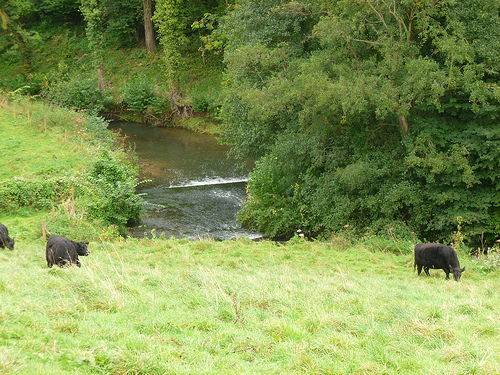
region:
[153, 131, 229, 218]
this is a water body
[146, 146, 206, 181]
the water is calm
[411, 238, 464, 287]
this is a cow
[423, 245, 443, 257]
the cow is black in color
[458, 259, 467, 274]
this is the horn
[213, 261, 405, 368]
this is a grass area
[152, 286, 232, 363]
the grass is green in color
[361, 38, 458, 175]
this is a tree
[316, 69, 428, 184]
the leaves are green in color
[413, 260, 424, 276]
this is the leg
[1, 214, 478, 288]
three cows in the grass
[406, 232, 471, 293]
a cow eating grass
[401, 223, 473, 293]
a black cow looking down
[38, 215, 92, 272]
a cow walking in the grass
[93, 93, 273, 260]
a small bubbling river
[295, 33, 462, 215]
dark green trees in the back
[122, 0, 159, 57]
a bare brown tree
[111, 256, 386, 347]
a field of green grass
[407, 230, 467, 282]
a black cow facing right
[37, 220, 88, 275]
a black cow facing back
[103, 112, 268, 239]
Flowing water down the hill.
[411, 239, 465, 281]
A black cow to the right of the water.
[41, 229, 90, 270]
Black cow turning around backwards.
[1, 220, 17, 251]
Black cow that is barely visible.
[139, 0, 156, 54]
The lngest brown non leaf covered tree trunk on the bank.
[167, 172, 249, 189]
A long white line of splashing water.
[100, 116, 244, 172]
Section of calmer water on down the bend.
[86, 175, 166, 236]
A green fern at the top of the water bank.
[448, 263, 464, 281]
The black head of a cow to the right of the water.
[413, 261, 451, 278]
Three visible black legs of a black cow to the right of the water.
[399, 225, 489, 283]
A black cow grazing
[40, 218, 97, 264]
A black cow grazing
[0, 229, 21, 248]
A black cow grazing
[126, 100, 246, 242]
A clear water stream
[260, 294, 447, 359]
A brown and green grass field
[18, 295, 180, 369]
A brown and green grass field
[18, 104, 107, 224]
A brown and green grass field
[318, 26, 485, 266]
A green thick forest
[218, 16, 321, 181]
A green thick forest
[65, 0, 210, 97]
A green thick forest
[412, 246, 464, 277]
a cow grazing on grass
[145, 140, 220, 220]
a stream of water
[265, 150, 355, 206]
leaves of a tree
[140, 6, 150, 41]
a trunk of a tree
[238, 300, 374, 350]
green grazing grass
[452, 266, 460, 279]
the head of a cow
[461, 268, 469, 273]
the ear of a cow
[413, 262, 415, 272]
the tail of a cow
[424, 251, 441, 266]
the stomach of a cow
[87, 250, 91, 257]
the mouth of a cow